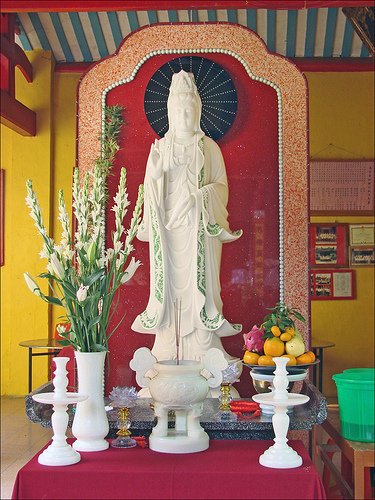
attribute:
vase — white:
[73, 348, 110, 455]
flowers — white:
[26, 107, 146, 350]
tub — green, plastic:
[333, 368, 374, 440]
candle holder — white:
[252, 355, 310, 468]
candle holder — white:
[32, 356, 88, 468]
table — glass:
[21, 338, 73, 395]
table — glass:
[310, 341, 335, 388]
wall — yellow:
[0, 52, 374, 393]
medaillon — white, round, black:
[143, 54, 238, 140]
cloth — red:
[14, 435, 326, 498]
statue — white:
[135, 54, 243, 361]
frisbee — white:
[165, 194, 192, 230]